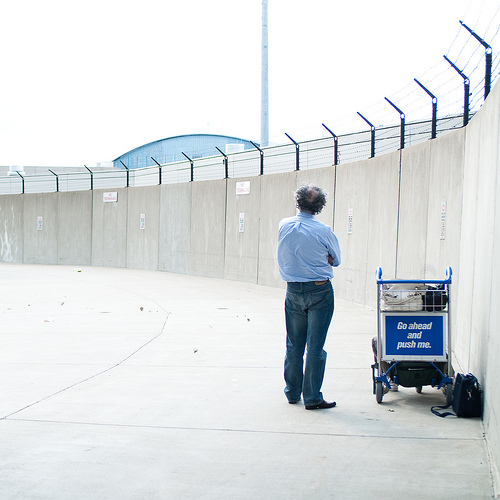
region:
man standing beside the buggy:
[259, 177, 459, 427]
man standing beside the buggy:
[262, 168, 454, 410]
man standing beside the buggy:
[268, 175, 449, 406]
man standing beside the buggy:
[227, 150, 451, 419]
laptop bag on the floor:
[431, 359, 486, 423]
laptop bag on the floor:
[426, 357, 498, 434]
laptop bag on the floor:
[420, 353, 492, 450]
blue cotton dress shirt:
[275, 212, 340, 282]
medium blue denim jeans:
[281, 278, 334, 400]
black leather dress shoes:
[306, 399, 337, 409]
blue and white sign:
[383, 312, 449, 362]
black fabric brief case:
[451, 372, 481, 416]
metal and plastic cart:
[368, 270, 455, 409]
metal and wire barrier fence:
[1, 15, 499, 195]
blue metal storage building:
[102, 133, 258, 165]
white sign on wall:
[236, 182, 250, 198]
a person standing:
[272, 180, 346, 415]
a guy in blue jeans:
[268, 181, 341, 414]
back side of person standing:
[271, 183, 343, 412]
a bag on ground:
[427, 370, 486, 422]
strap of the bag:
[427, 400, 455, 419]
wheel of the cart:
[373, 378, 385, 404]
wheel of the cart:
[441, 380, 455, 409]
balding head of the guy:
[292, 182, 330, 215]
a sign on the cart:
[378, 310, 450, 362]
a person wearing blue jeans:
[271, 180, 342, 414]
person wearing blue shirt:
[272, 182, 342, 412]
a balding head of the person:
[293, 183, 327, 215]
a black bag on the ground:
[427, 371, 486, 423]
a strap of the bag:
[429, 393, 456, 419]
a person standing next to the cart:
[271, 181, 459, 414]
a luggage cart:
[366, 263, 458, 406]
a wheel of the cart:
[372, 380, 385, 406]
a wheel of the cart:
[442, 381, 454, 408]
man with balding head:
[275, 183, 339, 413]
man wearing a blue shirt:
[271, 184, 343, 411]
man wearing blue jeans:
[273, 185, 339, 412]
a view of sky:
[150, 41, 217, 81]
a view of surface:
[171, 386, 269, 463]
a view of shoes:
[286, 339, 352, 431]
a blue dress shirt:
[273, 210, 338, 284]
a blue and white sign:
[379, 318, 443, 363]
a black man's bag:
[437, 365, 484, 422]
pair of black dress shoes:
[280, 390, 339, 421]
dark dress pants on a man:
[279, 275, 334, 409]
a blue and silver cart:
[370, 269, 460, 409]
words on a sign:
[387, 317, 443, 367]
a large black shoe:
[301, 387, 338, 408]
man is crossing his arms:
[275, 185, 343, 406]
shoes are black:
[286, 399, 337, 410]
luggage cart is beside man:
[371, 265, 456, 407]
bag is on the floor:
[430, 372, 485, 419]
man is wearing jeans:
[278, 178, 339, 410]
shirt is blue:
[275, 209, 342, 283]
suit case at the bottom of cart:
[388, 360, 449, 385]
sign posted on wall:
[102, 192, 117, 202]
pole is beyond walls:
[260, 0, 269, 148]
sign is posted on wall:
[235, 179, 250, 195]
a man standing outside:
[256, 180, 340, 437]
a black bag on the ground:
[446, 354, 476, 423]